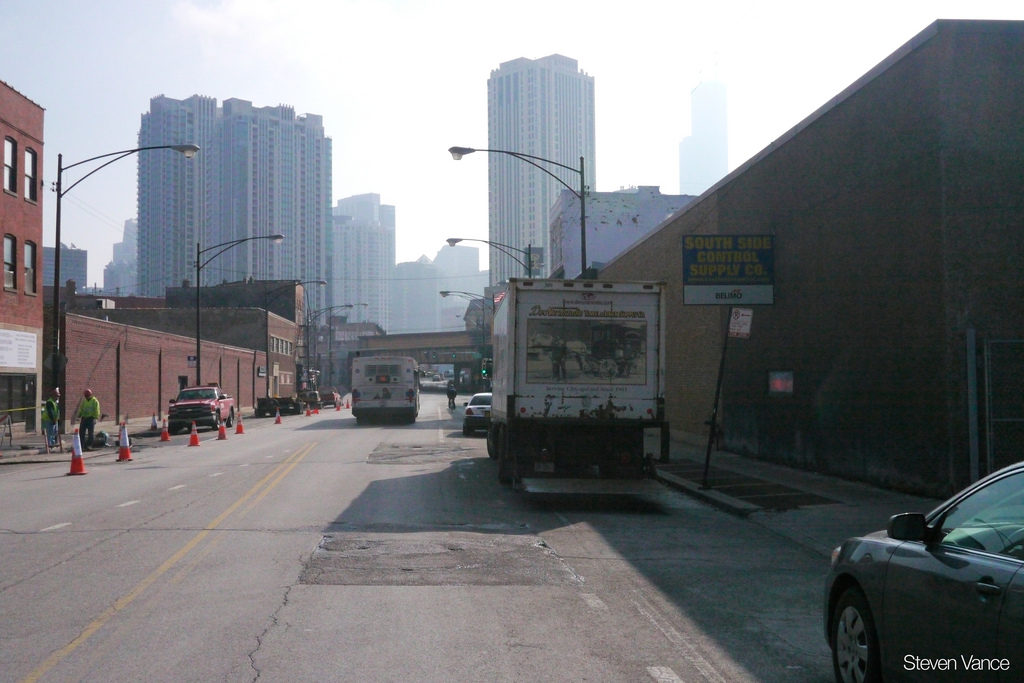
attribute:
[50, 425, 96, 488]
cone — traffic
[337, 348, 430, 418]
bus — white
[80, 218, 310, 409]
truck — red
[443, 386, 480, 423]
car — white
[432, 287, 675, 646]
truck — white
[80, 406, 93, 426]
shirt — green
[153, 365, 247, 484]
pickup truck — red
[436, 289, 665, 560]
delivery truck — white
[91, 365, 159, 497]
cones — orange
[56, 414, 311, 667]
lines — yellow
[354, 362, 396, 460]
bus — white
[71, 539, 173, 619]
line — double and  yellow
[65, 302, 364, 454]
traffic cones — orange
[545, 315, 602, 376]
truck — white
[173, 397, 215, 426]
pick-up truck — red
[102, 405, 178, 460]
cones — orange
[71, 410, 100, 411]
vests — yellow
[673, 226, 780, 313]
sign — blue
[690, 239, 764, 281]
lettering — yellow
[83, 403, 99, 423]
jacket — green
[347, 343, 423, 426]
bus — white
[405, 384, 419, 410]
brake light — red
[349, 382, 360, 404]
brake light — red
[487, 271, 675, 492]
truck — white, black, parked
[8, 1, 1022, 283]
sky — sunny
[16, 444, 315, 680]
lines — yellow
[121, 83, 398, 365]
sky scrapers — large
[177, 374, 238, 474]
pickup truck — red